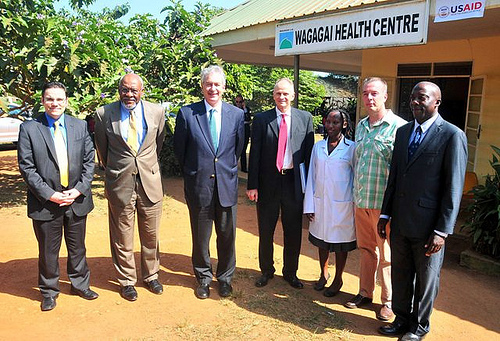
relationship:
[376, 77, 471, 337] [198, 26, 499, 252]
person in front of health center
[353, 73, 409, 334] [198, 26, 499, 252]
person in front of health center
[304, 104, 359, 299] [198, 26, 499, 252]
person in front of health center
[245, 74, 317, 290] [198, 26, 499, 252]
man in front of health center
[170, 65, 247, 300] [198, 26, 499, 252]
man in front of health center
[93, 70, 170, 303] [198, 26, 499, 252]
man in front of health center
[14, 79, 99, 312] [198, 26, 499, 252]
man in front of health center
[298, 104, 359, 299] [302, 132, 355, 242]
person wearing coat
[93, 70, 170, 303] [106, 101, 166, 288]
man wearing suit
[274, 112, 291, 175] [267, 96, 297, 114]
tie around neck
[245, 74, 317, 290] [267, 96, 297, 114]
man has neck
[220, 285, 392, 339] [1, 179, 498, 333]
shadow in dirt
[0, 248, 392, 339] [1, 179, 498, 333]
shadow in dirt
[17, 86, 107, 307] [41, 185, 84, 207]
man has hands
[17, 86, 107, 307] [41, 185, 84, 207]
man clasping hands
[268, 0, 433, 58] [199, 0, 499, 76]
sign underneath roof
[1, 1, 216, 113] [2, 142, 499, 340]
trees in path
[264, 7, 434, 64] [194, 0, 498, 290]
sign hanging on building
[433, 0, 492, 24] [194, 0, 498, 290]
sign hanging on building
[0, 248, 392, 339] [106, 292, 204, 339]
shadow on ground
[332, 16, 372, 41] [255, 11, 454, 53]
word on sign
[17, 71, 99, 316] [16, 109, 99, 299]
man in suit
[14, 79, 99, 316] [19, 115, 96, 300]
man wearing suit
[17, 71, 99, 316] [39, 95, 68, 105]
man wearing glasses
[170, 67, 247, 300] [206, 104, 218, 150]
man wearing tie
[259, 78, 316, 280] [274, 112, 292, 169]
man wearing tie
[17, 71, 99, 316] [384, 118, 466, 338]
man wearing suit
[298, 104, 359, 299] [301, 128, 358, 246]
person wearing coat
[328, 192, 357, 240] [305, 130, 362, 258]
pocket in coat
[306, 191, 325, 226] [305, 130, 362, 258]
pocket in coat